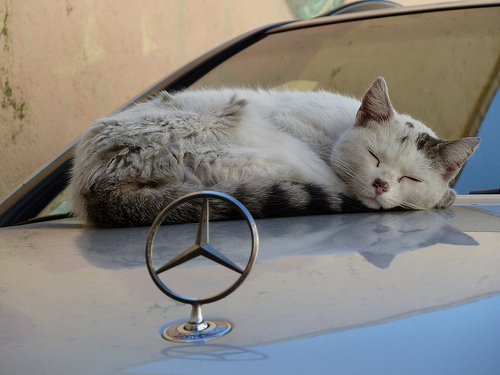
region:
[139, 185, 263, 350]
Round metallic grey insignia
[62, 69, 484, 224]
Cat laying sound asleep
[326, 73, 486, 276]
Cat's head and its shadow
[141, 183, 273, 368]
Insignia and its shadow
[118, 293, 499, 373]
Shade of blue color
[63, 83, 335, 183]
bushy light grey color of fur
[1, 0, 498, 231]
Door of a car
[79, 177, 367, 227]
Grey and black colored tail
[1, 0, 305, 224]
Brown painted wall with dirt marks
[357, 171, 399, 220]
Short snout of a cat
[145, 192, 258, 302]
the mercedes logo on the car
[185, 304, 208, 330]
the small stand for the mercede's logo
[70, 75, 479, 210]
the cat sleeping on the hood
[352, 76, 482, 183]
the ears on the cat's head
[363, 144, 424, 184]
the eyes on the cat's head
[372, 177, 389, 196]
the nose on the cat's head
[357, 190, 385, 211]
the mouth on the cat's head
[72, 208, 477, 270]
the reflection of the cat on the hood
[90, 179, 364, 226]
the tail on the cat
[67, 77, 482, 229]
the hair all over the cat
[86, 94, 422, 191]
this is a cat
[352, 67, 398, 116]
this is the ear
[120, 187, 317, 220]
this is the tail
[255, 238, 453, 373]
this is the car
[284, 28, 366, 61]
this is the windscreen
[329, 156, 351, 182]
this is the fur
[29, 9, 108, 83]
this is the wall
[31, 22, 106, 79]
the wall is cream in color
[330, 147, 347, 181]
the fur is white in color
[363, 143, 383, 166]
this is the eye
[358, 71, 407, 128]
ear of a cat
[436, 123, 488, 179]
left ear of cat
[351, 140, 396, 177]
eye of the cat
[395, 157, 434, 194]
left eye of the cat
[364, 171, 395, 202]
nose of the cat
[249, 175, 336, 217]
light and dark tail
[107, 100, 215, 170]
fur on the back of the cat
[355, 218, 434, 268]
reflection of the cat in the car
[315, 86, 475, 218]
cat with eyes closed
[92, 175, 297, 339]
symbol on a car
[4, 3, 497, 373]
A Mercedes emblem is on the car.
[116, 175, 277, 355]
The Mercedes emblem is silver.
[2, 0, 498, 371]
The cat is lying on the car.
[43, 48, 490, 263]
The cat is furry.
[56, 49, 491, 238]
The cat is long-haired.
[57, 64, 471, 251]
The cat is sleeping.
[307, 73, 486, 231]
The cat has whiskers.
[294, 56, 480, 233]
The cat's nose is pink.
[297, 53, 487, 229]
The cat has two ears.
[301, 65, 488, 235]
The cat's eyes are closed.